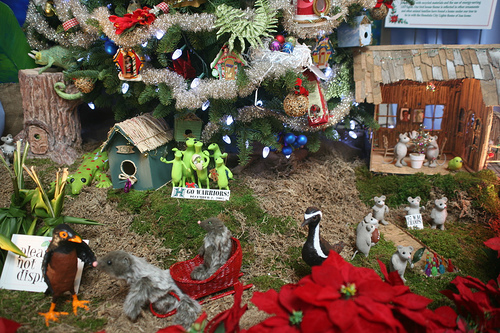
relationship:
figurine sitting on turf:
[33, 218, 105, 331] [26, 312, 116, 330]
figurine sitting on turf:
[209, 153, 236, 192] [140, 183, 255, 248]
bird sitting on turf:
[301, 206, 346, 269] [263, 224, 299, 277]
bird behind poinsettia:
[298, 205, 325, 262] [312, 264, 372, 326]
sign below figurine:
[169, 185, 233, 203] [160, 148, 191, 188]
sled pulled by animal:
[146, 235, 254, 319] [91, 250, 197, 328]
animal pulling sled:
[91, 250, 197, 328] [146, 235, 254, 319]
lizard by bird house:
[47, 142, 114, 195] [99, 111, 180, 191]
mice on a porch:
[388, 131, 409, 169] [366, 146, 474, 176]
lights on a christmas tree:
[153, 28, 255, 152] [23, 0, 414, 165]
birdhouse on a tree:
[334, 13, 376, 48] [24, 0, 361, 175]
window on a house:
[422, 102, 446, 131] [352, 43, 499, 181]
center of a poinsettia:
[325, 273, 360, 303] [252, 253, 458, 332]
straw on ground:
[267, 157, 332, 227] [2, 39, 495, 331]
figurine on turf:
[432, 197, 451, 230] [15, 137, 499, 322]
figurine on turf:
[379, 239, 422, 294] [289, 166, 489, 316]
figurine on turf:
[35, 225, 99, 317] [2, 188, 116, 328]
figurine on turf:
[208, 141, 231, 192] [169, 202, 227, 211]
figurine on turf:
[187, 139, 212, 188] [169, 202, 227, 211]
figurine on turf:
[154, 146, 191, 188] [169, 202, 227, 211]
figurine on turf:
[427, 197, 447, 229] [416, 232, 456, 241]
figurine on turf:
[403, 195, 424, 227] [416, 232, 456, 241]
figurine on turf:
[372, 195, 392, 223] [416, 232, 456, 241]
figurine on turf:
[392, 245, 415, 280] [416, 232, 456, 241]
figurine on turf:
[354, 213, 381, 258] [416, 232, 456, 241]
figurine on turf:
[130, 129, 265, 211] [144, 137, 249, 233]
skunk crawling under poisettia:
[294, 194, 351, 270] [239, 248, 424, 328]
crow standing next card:
[40, 223, 93, 325] [1, 233, 88, 296]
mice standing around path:
[357, 189, 451, 276] [386, 227, 432, 267]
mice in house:
[394, 124, 442, 179] [352, 43, 499, 181]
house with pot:
[352, 43, 499, 181] [407, 146, 424, 169]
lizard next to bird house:
[70, 129, 120, 188] [108, 110, 181, 187]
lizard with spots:
[70, 129, 120, 188] [78, 151, 108, 180]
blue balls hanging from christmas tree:
[281, 129, 309, 156] [26, 2, 413, 164]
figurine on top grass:
[172, 136, 211, 189] [123, 162, 284, 249]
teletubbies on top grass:
[401, 188, 448, 226] [136, 171, 272, 257]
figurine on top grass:
[208, 157, 236, 192] [141, 203, 194, 241]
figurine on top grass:
[160, 148, 191, 188] [130, 159, 292, 262]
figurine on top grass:
[172, 136, 211, 189] [130, 159, 292, 262]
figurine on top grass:
[208, 157, 236, 192] [130, 159, 292, 262]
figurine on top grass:
[208, 143, 228, 168] [130, 159, 292, 262]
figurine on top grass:
[189, 140, 210, 189] [137, 163, 289, 246]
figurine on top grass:
[208, 157, 236, 192] [125, 200, 205, 236]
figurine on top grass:
[160, 148, 191, 188] [125, 200, 205, 236]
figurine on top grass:
[189, 140, 210, 189] [125, 200, 205, 236]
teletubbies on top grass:
[106, 46, 150, 88] [138, 154, 260, 245]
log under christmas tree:
[19, 63, 96, 171] [21, 2, 380, 165]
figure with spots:
[60, 131, 118, 200] [72, 147, 108, 177]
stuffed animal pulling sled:
[98, 248, 201, 328] [149, 237, 253, 318]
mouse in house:
[426, 195, 448, 228] [352, 43, 500, 177]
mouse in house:
[400, 191, 423, 226] [352, 43, 500, 177]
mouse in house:
[368, 189, 385, 220] [352, 43, 500, 177]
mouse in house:
[390, 130, 411, 167] [352, 43, 500, 177]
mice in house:
[422, 135, 447, 168] [352, 43, 500, 177]